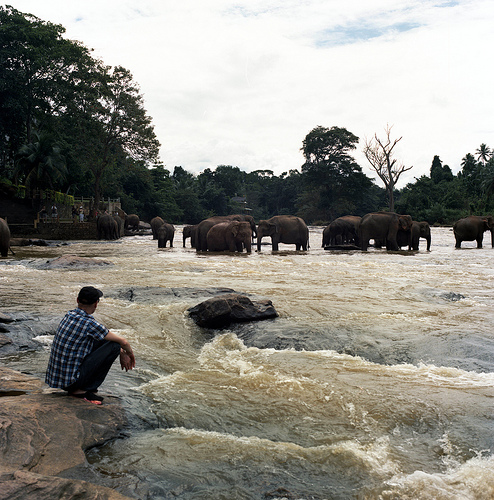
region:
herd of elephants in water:
[141, 183, 493, 276]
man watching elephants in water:
[34, 180, 492, 427]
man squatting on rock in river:
[42, 270, 166, 410]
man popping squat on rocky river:
[46, 277, 138, 408]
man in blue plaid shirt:
[49, 281, 129, 389]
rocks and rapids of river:
[163, 274, 400, 453]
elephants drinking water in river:
[180, 213, 316, 266]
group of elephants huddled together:
[316, 195, 443, 257]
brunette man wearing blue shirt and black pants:
[46, 274, 151, 413]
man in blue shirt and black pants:
[50, 274, 134, 408]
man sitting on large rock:
[42, 277, 125, 407]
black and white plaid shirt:
[38, 310, 107, 379]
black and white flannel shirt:
[38, 315, 101, 380]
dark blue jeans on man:
[73, 334, 125, 391]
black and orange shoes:
[80, 393, 100, 406]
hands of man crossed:
[112, 338, 141, 371]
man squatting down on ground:
[8, 274, 133, 403]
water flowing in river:
[222, 336, 417, 471]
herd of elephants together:
[124, 197, 445, 270]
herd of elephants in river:
[139, 199, 426, 256]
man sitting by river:
[43, 281, 136, 404]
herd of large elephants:
[122, 209, 492, 256]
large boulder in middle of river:
[184, 290, 277, 332]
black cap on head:
[73, 282, 104, 313]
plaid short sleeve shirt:
[45, 309, 108, 392]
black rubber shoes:
[71, 389, 102, 402]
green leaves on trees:
[2, 95, 491, 224]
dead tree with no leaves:
[361, 122, 414, 215]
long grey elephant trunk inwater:
[425, 237, 432, 251]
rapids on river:
[133, 317, 492, 497]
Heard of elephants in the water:
[97, 206, 492, 265]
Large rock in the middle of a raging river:
[168, 280, 290, 342]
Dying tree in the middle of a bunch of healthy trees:
[360, 125, 415, 220]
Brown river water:
[152, 314, 437, 489]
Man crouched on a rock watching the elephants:
[42, 268, 139, 418]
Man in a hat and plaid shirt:
[41, 276, 141, 413]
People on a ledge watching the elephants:
[33, 195, 114, 226]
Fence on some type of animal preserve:
[23, 183, 126, 220]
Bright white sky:
[6, 2, 491, 186]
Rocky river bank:
[1, 305, 146, 498]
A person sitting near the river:
[15, 109, 493, 480]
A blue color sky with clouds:
[272, 20, 444, 90]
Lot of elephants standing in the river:
[101, 197, 492, 254]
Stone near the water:
[141, 284, 277, 327]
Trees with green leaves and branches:
[6, 21, 127, 171]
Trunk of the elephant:
[238, 234, 264, 258]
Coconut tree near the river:
[457, 139, 489, 161]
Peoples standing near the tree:
[47, 200, 90, 225]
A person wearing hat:
[66, 284, 113, 303]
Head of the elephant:
[232, 219, 274, 251]